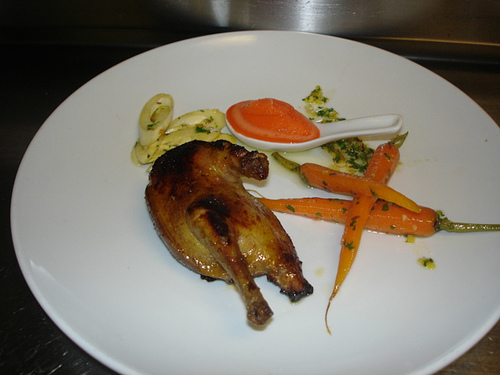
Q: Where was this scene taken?
A: A restaurant.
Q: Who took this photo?
A: A professional photographer.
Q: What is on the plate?
A: Cornish hen and veggies.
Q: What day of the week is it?
A: Tuesday.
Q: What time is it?
A: Noon.